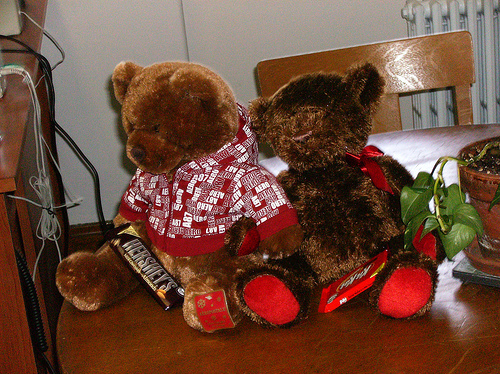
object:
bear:
[58, 56, 298, 333]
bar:
[107, 224, 187, 312]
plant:
[399, 137, 500, 279]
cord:
[18, 68, 70, 282]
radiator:
[399, 2, 499, 125]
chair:
[257, 29, 477, 132]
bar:
[313, 252, 390, 313]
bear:
[225, 63, 434, 329]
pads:
[241, 274, 304, 326]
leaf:
[398, 171, 433, 230]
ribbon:
[347, 143, 399, 195]